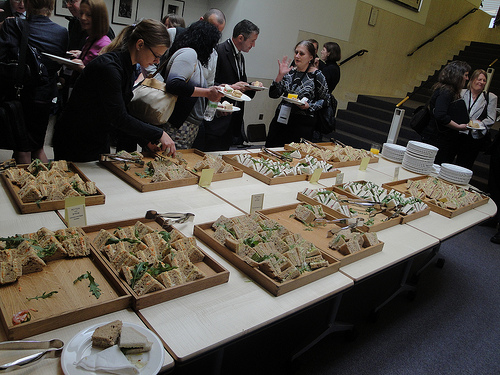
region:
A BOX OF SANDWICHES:
[6, 201, 228, 340]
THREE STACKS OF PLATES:
[376, 134, 481, 189]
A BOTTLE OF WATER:
[201, 92, 223, 126]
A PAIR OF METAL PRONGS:
[4, 334, 72, 369]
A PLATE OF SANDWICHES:
[51, 316, 169, 374]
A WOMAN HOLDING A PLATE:
[264, 26, 343, 149]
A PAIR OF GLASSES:
[141, 43, 171, 68]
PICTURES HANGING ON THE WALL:
[39, 1, 211, 36]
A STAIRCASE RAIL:
[401, 4, 493, 68]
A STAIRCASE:
[336, 27, 495, 153]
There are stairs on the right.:
[323, 30, 499, 152]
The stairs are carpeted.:
[328, 21, 498, 163]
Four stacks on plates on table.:
[376, 134, 476, 194]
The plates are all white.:
[369, 125, 474, 195]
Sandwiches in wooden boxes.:
[76, 205, 241, 309]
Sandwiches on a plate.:
[61, 318, 165, 373]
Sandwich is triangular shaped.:
[116, 321, 156, 356]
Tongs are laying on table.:
[0, 336, 70, 373]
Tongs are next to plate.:
[0, 331, 72, 373]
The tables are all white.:
[1, 132, 496, 373]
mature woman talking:
[265, 37, 330, 147]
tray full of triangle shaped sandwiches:
[80, 211, 225, 304]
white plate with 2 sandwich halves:
[60, 318, 165, 374]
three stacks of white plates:
[380, 141, 475, 186]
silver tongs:
[0, 337, 65, 374]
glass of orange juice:
[366, 139, 380, 157]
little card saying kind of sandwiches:
[248, 190, 263, 214]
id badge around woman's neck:
[278, 99, 291, 124]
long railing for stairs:
[403, 2, 480, 60]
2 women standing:
[414, 54, 496, 178]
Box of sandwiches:
[191, 210, 330, 286]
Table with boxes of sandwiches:
[66, 165, 423, 285]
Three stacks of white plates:
[368, 121, 492, 193]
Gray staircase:
[358, 73, 416, 166]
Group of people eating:
[43, 24, 351, 173]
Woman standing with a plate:
[268, 39, 343, 144]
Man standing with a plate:
[222, 20, 282, 149]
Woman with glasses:
[72, 6, 177, 171]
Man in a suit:
[201, 18, 261, 142]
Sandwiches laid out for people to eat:
[74, 157, 440, 271]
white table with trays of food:
[43, 152, 353, 363]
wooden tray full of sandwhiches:
[192, 207, 337, 297]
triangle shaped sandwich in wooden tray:
[260, 255, 280, 280]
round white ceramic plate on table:
[61, 320, 161, 370]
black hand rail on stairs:
[405, 2, 475, 57]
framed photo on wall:
[111, 0, 136, 25]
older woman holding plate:
[260, 35, 326, 140]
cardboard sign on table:
[246, 190, 261, 212]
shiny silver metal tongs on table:
[0, 335, 60, 370]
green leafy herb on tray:
[70, 270, 100, 300]